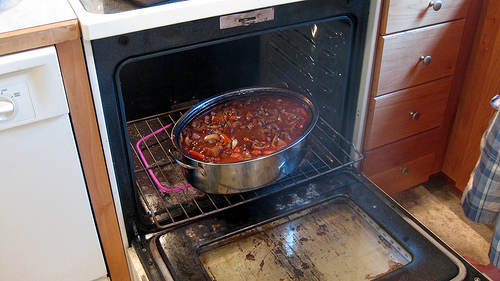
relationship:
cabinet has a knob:
[358, 0, 470, 194] [423, 55, 431, 67]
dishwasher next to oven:
[0, 46, 113, 281] [114, 17, 481, 279]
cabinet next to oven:
[358, 0, 470, 194] [114, 17, 481, 279]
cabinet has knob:
[358, 0, 470, 194] [423, 55, 431, 67]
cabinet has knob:
[358, 0, 470, 194] [428, 1, 442, 13]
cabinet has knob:
[358, 0, 470, 194] [408, 111, 420, 120]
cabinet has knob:
[358, 0, 470, 194] [398, 166, 410, 177]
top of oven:
[69, 1, 311, 41] [114, 17, 481, 279]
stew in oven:
[179, 93, 312, 164] [114, 17, 481, 279]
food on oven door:
[185, 221, 327, 270] [127, 165, 493, 280]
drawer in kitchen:
[378, 0, 468, 37] [0, 0, 499, 280]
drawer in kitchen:
[373, 17, 467, 96] [0, 0, 499, 280]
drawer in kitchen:
[362, 73, 455, 149] [0, 0, 499, 280]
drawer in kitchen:
[359, 125, 439, 189] [0, 0, 499, 280]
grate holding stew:
[127, 82, 364, 229] [179, 93, 312, 164]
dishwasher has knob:
[0, 46, 113, 281] [0, 100, 17, 124]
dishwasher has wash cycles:
[0, 46, 113, 281] [1, 91, 25, 125]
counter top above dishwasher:
[0, 1, 79, 57] [0, 46, 113, 281]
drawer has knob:
[378, 0, 468, 37] [428, 1, 442, 13]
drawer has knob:
[373, 17, 467, 96] [423, 55, 431, 67]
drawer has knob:
[362, 73, 455, 149] [408, 111, 420, 120]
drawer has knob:
[359, 125, 439, 189] [398, 166, 410, 177]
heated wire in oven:
[136, 120, 191, 192] [114, 17, 481, 279]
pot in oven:
[169, 87, 318, 194] [114, 17, 481, 279]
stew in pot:
[179, 93, 312, 164] [169, 87, 318, 194]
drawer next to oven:
[378, 0, 468, 37] [114, 17, 481, 279]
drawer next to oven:
[373, 17, 467, 96] [114, 17, 481, 279]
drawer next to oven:
[362, 73, 455, 149] [114, 17, 481, 279]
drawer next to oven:
[359, 125, 439, 189] [114, 17, 481, 279]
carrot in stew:
[220, 132, 231, 144] [179, 93, 312, 164]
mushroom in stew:
[203, 134, 220, 141] [179, 93, 312, 164]